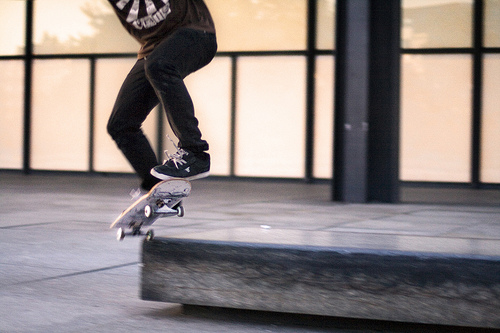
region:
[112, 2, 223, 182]
the skateboarder in black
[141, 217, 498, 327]
the bench the man is skating on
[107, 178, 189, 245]
the white skateboard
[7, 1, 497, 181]
the building along the back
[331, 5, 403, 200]
the pole next to the building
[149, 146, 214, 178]
the black shoe on the foot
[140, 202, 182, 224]
the front wheels of the board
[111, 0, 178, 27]
the writing on the shirt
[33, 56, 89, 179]
part of the wall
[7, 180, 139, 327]
the ground made of concrete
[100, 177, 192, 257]
Skateboard in the air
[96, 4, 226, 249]
A person doing a trick on a skateboard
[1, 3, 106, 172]
Pink-tinted windows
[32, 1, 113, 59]
Trees in the background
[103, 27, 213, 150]
A pair of black jeans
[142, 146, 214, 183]
One black skateboarding shoe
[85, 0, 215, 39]
The bottom part of a brown t-shirt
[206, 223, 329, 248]
The reflection of a window on a shiny surface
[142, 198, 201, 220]
The front wheels of a skateboard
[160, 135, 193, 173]
White shoelaces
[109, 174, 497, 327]
a skate board goes over a block of cement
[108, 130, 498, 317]
a person wearing black shoes is skateboarding on a piece of cement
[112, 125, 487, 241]
a skateboarder who is wearing black shoes is jumping on the edge of a cement block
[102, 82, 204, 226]
A skateboarder is doing tricks on his skateboard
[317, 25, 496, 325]
A steel beam stands behind a piece of concrete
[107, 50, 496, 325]
The skateboarder is doing tricks on the concrete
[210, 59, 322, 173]
Pink window with black bar is where skateboarder is doing tricks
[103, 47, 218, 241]
Knees are bent while skateboarder is doing tricks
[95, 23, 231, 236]
Skateboarder is wearing black pants and black shoes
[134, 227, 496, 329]
The concrete slab is grey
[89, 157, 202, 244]
skateboard goes airborne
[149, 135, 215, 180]
blacdk sneaker with white laces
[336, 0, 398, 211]
steel girder with riviets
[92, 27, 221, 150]
Black pair of jeans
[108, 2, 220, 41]
black t-shirt with white design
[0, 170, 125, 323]
concrete section of flooring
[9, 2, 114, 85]
trees show through frosted windows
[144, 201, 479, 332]
a step to practice jumps with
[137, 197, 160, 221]
a white skateboard wheel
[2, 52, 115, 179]
opaque windows around the floor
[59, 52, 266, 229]
One person is skating.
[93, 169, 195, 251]
Skate board is white with red borders.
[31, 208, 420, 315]
Floor is grey color.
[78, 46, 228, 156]
Person is wearing black pants.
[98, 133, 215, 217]
Sneakers is black color.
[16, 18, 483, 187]
Frames are black color.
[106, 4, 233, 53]
person is wearing brown shirt.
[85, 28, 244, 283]
Person is doing a trick in skating.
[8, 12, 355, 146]
reflection of trees are seen in window.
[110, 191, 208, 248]
Wheels are white color.